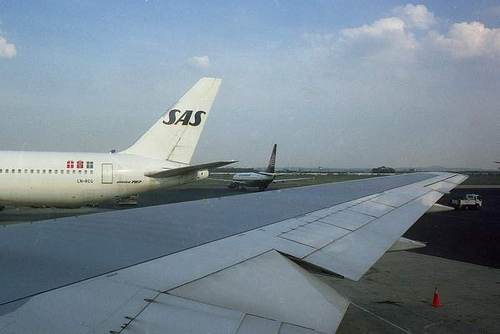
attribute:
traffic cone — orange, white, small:
[426, 286, 443, 308]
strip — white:
[433, 290, 439, 296]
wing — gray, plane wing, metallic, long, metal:
[3, 169, 467, 334]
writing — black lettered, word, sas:
[161, 106, 205, 125]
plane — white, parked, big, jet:
[1, 52, 243, 212]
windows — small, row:
[1, 165, 94, 175]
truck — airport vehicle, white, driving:
[452, 190, 484, 215]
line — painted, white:
[349, 300, 426, 333]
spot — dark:
[373, 297, 408, 309]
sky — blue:
[2, 4, 498, 179]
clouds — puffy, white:
[313, 8, 497, 76]